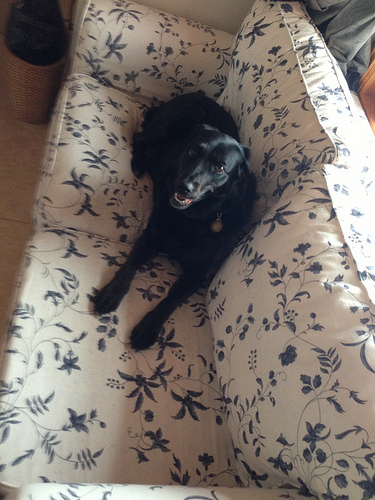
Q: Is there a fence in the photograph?
A: No, there are no fences.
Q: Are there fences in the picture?
A: No, there are no fences.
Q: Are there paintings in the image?
A: No, there are no paintings.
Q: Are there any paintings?
A: No, there are no paintings.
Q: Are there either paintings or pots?
A: No, there are no paintings or pots.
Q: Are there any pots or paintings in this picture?
A: No, there are no paintings or pots.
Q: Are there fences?
A: No, there are no fences.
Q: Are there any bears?
A: No, there are no bears.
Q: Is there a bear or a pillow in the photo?
A: No, there are no bears or pillows.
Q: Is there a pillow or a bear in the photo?
A: No, there are no bears or pillows.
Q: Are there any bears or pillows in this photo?
A: No, there are no bears or pillows.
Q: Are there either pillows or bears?
A: No, there are no bears or pillows.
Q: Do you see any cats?
A: No, there are no cats.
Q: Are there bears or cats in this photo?
A: No, there are no cats or bears.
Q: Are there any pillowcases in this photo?
A: No, there are no pillowcases.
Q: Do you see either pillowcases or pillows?
A: No, there are no pillowcases or pillows.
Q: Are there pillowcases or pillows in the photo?
A: No, there are no pillowcases or pillows.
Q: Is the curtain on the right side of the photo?
A: Yes, the curtain is on the right of the image.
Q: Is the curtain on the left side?
A: No, the curtain is on the right of the image.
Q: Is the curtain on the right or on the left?
A: The curtain is on the right of the image.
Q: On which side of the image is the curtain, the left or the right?
A: The curtain is on the right of the image.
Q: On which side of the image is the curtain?
A: The curtain is on the right of the image.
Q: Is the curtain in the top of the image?
A: Yes, the curtain is in the top of the image.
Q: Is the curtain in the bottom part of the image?
A: No, the curtain is in the top of the image.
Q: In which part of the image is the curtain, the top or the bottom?
A: The curtain is in the top of the image.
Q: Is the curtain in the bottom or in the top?
A: The curtain is in the top of the image.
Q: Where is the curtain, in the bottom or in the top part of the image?
A: The curtain is in the top of the image.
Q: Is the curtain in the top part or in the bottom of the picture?
A: The curtain is in the top of the image.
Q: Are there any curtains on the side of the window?
A: Yes, there is a curtain on the side of the window.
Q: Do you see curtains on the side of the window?
A: Yes, there is a curtain on the side of the window.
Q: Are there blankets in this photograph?
A: No, there are no blankets.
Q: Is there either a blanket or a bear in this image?
A: No, there are no blankets or bears.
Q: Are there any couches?
A: Yes, there is a couch.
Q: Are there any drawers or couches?
A: Yes, there is a couch.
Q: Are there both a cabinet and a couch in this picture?
A: No, there is a couch but no cabinets.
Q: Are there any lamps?
A: No, there are no lamps.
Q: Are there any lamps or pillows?
A: No, there are no lamps or pillows.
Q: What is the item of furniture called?
A: The piece of furniture is a couch.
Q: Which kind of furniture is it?
A: The piece of furniture is a couch.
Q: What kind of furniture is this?
A: This is a couch.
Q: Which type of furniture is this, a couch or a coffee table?
A: This is a couch.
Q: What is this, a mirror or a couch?
A: This is a couch.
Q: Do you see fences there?
A: No, there are no fences.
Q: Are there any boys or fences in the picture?
A: No, there are no fences or boys.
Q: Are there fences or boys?
A: No, there are no fences or boys.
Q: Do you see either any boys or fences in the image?
A: No, there are no fences or boys.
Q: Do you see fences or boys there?
A: No, there are no fences or boys.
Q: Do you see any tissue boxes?
A: No, there are no tissue boxes.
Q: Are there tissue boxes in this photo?
A: No, there are no tissue boxes.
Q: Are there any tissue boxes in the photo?
A: No, there are no tissue boxes.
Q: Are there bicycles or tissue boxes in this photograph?
A: No, there are no tissue boxes or bicycles.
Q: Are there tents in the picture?
A: No, there are no tents.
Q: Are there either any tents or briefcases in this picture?
A: No, there are no tents or briefcases.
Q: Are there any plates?
A: No, there are no plates.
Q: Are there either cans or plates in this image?
A: No, there are no plates or cans.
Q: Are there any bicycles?
A: No, there are no bicycles.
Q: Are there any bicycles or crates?
A: No, there are no bicycles or crates.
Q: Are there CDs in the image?
A: No, there are no cds.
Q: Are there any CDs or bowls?
A: No, there are no CDs or bowls.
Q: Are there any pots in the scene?
A: No, there are no pots.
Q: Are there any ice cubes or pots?
A: No, there are no pots or ice cubes.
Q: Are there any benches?
A: No, there are no benches.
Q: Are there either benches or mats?
A: No, there are no benches or mats.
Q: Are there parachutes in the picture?
A: No, there are no parachutes.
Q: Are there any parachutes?
A: No, there are no parachutes.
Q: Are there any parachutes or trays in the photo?
A: No, there are no parachutes or trays.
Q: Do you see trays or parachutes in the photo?
A: No, there are no parachutes or trays.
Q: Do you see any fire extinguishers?
A: No, there are no fire extinguishers.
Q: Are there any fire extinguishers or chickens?
A: No, there are no fire extinguishers or chickens.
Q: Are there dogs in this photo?
A: Yes, there is a dog.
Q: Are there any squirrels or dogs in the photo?
A: Yes, there is a dog.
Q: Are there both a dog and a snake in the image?
A: No, there is a dog but no snakes.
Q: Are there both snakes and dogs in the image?
A: No, there is a dog but no snakes.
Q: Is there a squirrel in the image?
A: No, there are no squirrels.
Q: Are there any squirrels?
A: No, there are no squirrels.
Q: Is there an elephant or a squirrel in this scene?
A: No, there are no squirrels or elephants.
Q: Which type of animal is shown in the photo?
A: The animal is a dog.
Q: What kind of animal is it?
A: The animal is a dog.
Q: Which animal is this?
A: This is a dog.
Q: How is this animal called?
A: This is a dog.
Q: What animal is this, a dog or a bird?
A: This is a dog.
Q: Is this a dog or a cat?
A: This is a dog.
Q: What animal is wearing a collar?
A: The dog is wearing a collar.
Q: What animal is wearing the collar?
A: The dog is wearing a collar.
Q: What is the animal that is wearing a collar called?
A: The animal is a dog.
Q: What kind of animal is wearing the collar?
A: The animal is a dog.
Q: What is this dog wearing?
A: The dog is wearing a collar.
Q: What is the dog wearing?
A: The dog is wearing a collar.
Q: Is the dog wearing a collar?
A: Yes, the dog is wearing a collar.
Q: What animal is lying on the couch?
A: The dog is lying on the couch.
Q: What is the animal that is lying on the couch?
A: The animal is a dog.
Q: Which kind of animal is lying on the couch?
A: The animal is a dog.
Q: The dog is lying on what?
A: The dog is lying on the couch.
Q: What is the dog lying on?
A: The dog is lying on the couch.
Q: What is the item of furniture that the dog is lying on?
A: The piece of furniture is a couch.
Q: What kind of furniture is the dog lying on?
A: The dog is lying on the couch.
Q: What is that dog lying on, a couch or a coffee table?
A: The dog is lying on a couch.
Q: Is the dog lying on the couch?
A: Yes, the dog is lying on the couch.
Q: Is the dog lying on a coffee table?
A: No, the dog is lying on the couch.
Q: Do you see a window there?
A: Yes, there is a window.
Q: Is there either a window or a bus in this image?
A: Yes, there is a window.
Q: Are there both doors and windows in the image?
A: No, there is a window but no doors.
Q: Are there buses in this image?
A: No, there are no buses.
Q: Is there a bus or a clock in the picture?
A: No, there are no buses or clocks.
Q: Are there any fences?
A: No, there are no fences.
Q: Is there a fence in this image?
A: No, there are no fences.